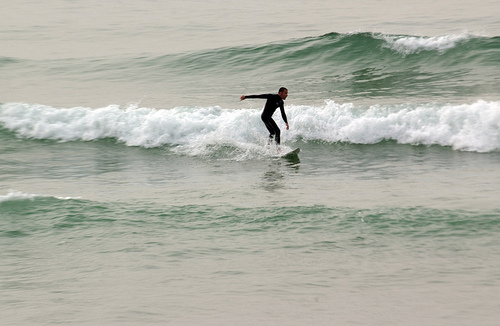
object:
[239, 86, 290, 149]
surfer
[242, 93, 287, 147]
wetsuit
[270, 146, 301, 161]
surfboard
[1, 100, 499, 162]
wave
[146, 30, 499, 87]
wave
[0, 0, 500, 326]
water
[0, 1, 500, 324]
ocean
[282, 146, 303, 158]
front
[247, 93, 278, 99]
arm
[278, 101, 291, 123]
arm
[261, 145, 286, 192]
reflection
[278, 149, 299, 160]
edge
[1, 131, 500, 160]
edge